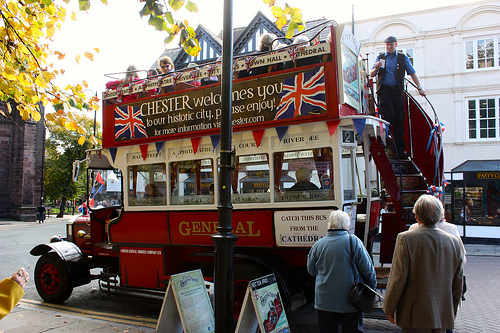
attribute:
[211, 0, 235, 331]
pole — tall, black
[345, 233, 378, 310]
purse — black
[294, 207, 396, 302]
hair — white, short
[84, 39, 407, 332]
bus — small, red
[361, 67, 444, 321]
stairwell — red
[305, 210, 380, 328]
person — white-haired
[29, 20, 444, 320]
bus — large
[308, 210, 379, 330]
lady — old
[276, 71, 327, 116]
flag — red, white, blue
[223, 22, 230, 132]
pole — black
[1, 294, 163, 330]
lines — yellow